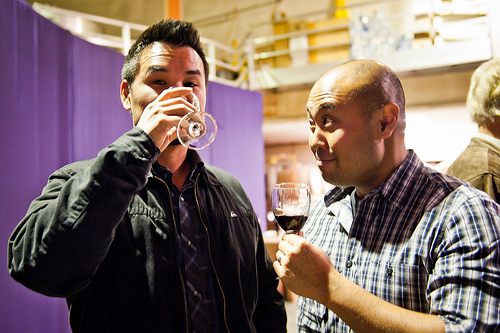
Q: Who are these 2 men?
A: Buddies.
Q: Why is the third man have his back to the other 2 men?
A: Not with them.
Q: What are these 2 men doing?
A: Drinking wine.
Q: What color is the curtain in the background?
A: Purple.